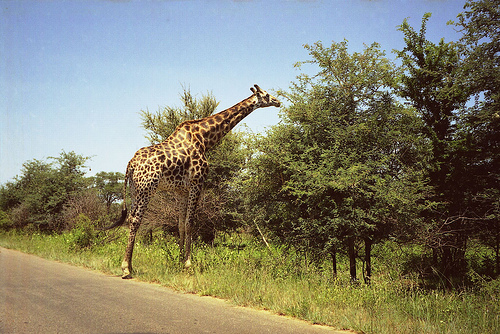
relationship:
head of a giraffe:
[250, 84, 281, 109] [114, 71, 288, 282]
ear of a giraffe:
[260, 91, 267, 98] [114, 71, 288, 282]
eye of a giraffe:
[262, 93, 273, 104] [114, 71, 288, 282]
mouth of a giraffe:
[270, 97, 281, 107] [114, 71, 288, 282]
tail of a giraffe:
[103, 158, 133, 233] [107, 83, 282, 280]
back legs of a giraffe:
[116, 171, 156, 282] [107, 83, 282, 280]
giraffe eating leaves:
[122, 84, 281, 279] [270, 42, 434, 252]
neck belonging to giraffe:
[205, 92, 255, 144] [114, 71, 288, 282]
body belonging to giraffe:
[152, 123, 192, 187] [122, 84, 281, 279]